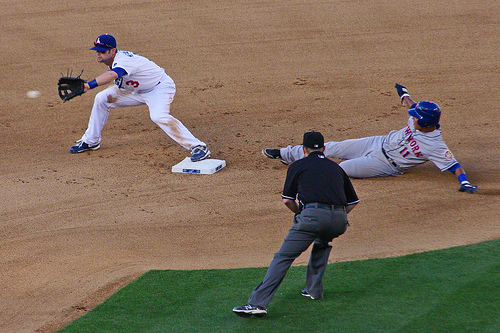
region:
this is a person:
[29, 13, 240, 231]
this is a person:
[221, 110, 377, 327]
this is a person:
[271, 66, 484, 214]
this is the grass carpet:
[135, 277, 185, 327]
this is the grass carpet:
[345, 282, 395, 327]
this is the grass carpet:
[152, 255, 212, 321]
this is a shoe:
[231, 285, 276, 325]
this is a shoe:
[175, 120, 218, 172]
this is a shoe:
[251, 125, 291, 176]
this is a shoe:
[51, 123, 111, 186]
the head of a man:
[88, 28, 125, 80]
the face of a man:
[89, 21, 128, 73]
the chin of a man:
[87, 53, 117, 70]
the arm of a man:
[68, 53, 144, 110]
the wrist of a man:
[74, 48, 109, 103]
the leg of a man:
[64, 47, 164, 167]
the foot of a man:
[51, 119, 113, 176]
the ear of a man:
[109, 30, 131, 58]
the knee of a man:
[134, 104, 166, 136]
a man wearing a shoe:
[67, 122, 109, 165]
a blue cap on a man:
[89, 32, 119, 54]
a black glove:
[55, 70, 84, 107]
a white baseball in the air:
[25, 86, 42, 103]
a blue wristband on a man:
[86, 72, 100, 94]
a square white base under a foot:
[170, 152, 230, 181]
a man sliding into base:
[257, 79, 480, 194]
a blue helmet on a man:
[409, 99, 443, 126]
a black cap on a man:
[299, 128, 329, 149]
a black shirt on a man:
[279, 149, 362, 211]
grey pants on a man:
[244, 204, 351, 306]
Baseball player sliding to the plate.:
[261, 76, 475, 195]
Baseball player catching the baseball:
[26, 28, 227, 165]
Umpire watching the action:
[233, 129, 360, 318]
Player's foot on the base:
[168, 139, 226, 175]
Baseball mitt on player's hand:
[55, 71, 90, 103]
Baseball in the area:
[27, 81, 41, 106]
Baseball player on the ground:
[261, 82, 478, 198]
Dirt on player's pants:
[158, 109, 188, 149]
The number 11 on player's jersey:
[398, 142, 413, 165]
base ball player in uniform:
[53, 32, 223, 169]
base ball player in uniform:
[262, 82, 484, 195]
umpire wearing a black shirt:
[227, 128, 361, 318]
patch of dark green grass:
[45, 225, 499, 331]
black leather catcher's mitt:
[47, 65, 92, 105]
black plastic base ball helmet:
[400, 98, 446, 130]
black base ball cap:
[297, 122, 332, 150]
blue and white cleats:
[62, 138, 107, 158]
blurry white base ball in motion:
[23, 85, 45, 98]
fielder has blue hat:
[66, 24, 134, 72]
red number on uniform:
[106, 61, 138, 91]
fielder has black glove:
[48, 59, 112, 112]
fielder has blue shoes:
[51, 105, 122, 169]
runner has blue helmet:
[399, 94, 451, 146]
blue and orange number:
[389, 132, 424, 171]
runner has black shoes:
[257, 136, 295, 163]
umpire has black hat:
[292, 125, 323, 146]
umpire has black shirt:
[267, 147, 353, 201]